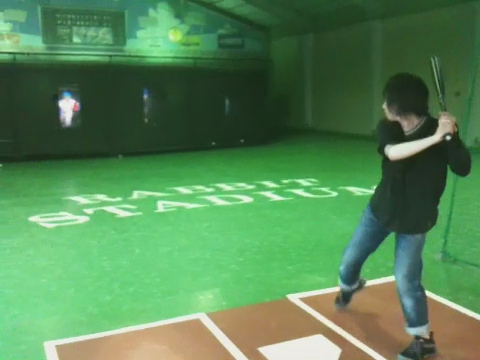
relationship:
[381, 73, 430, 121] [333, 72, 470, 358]
bo has hair on boy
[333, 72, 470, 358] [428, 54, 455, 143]
boy holding baseball bat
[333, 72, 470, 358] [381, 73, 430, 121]
boy has bo has hair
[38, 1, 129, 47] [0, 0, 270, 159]
scoreboard on wall